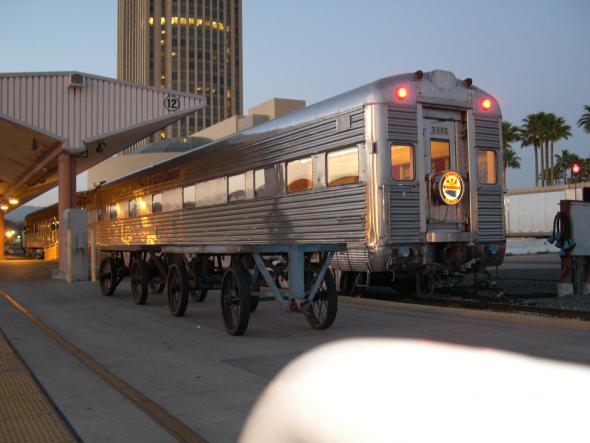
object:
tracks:
[89, 237, 589, 320]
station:
[0, 65, 384, 440]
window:
[220, 165, 252, 203]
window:
[177, 184, 202, 211]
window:
[123, 191, 140, 223]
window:
[177, 181, 200, 216]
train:
[23, 70, 511, 294]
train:
[85, 64, 507, 292]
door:
[420, 101, 470, 226]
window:
[285, 154, 315, 189]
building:
[117, 3, 241, 146]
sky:
[3, 1, 587, 101]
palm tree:
[519, 110, 571, 185]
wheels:
[339, 261, 382, 299]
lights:
[396, 82, 494, 110]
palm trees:
[514, 110, 571, 188]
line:
[2, 284, 202, 440]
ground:
[4, 255, 588, 437]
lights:
[152, 15, 229, 30]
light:
[564, 157, 580, 177]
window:
[470, 141, 505, 186]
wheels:
[213, 267, 260, 335]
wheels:
[154, 262, 196, 323]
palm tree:
[519, 109, 572, 199]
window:
[422, 134, 461, 176]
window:
[322, 144, 360, 189]